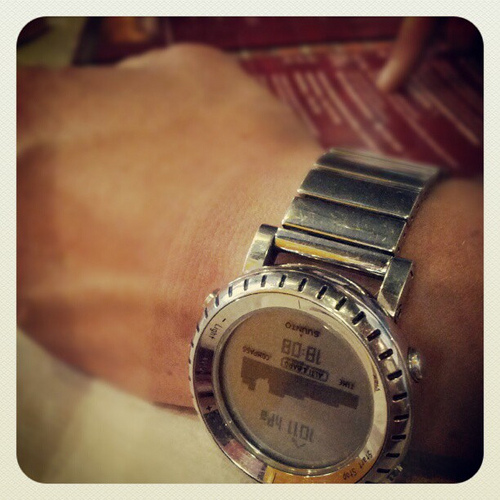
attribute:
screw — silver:
[405, 343, 428, 385]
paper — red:
[222, 42, 485, 185]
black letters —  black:
[278, 338, 322, 367]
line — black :
[240, 277, 250, 291]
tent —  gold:
[335, 462, 370, 479]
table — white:
[24, 407, 191, 478]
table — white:
[10, 312, 257, 499]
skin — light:
[16, 39, 482, 476]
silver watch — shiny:
[186, 140, 446, 483]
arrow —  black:
[287, 436, 307, 448]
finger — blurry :
[369, 9, 432, 105]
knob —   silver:
[396, 343, 431, 387]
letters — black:
[262, 324, 347, 376]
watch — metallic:
[190, 122, 416, 489]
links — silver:
[309, 163, 400, 233]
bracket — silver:
[245, 151, 441, 291]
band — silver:
[250, 141, 432, 273]